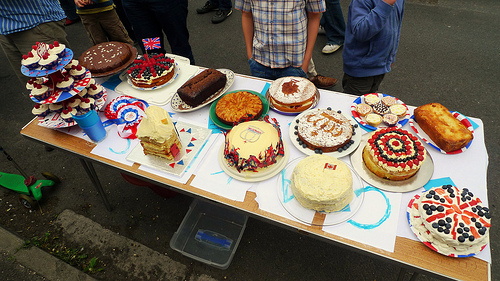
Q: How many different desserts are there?
A: Fourteen.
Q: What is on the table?
A: Many desserts.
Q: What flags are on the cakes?
A: Union Jack and Maple Leaf.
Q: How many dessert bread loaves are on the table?
A: Two.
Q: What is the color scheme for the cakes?
A: Red, white and blue.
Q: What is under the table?
A: A plastic bin.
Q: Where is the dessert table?
A: At a bake sale.